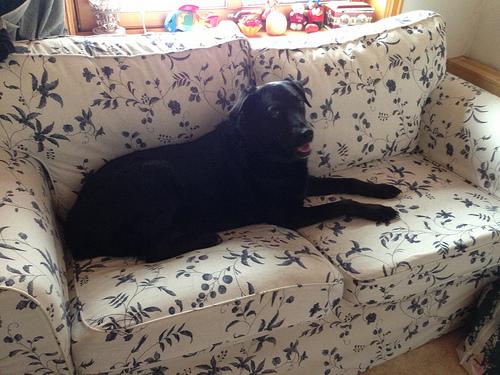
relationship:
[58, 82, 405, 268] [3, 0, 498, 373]
dog on sofa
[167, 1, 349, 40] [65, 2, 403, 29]
toys on window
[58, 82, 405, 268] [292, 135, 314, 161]
dog has mouth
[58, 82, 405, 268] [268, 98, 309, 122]
dog has eyes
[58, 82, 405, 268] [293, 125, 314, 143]
dog has nose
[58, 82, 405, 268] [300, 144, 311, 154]
dog has tongue